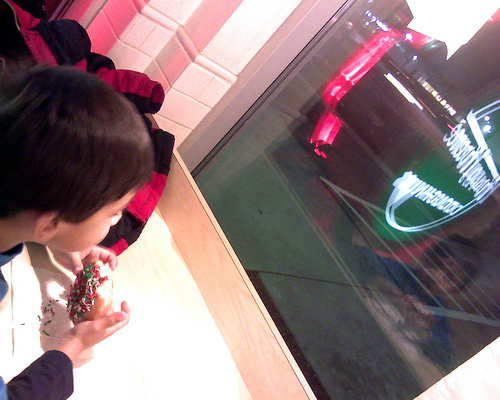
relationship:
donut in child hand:
[66, 260, 114, 326] [62, 248, 132, 353]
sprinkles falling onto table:
[25, 295, 59, 341] [24, 248, 283, 399]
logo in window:
[382, 86, 497, 244] [196, 5, 492, 399]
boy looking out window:
[0, 67, 154, 400] [196, 5, 492, 399]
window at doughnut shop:
[196, 5, 492, 399] [1, 2, 497, 396]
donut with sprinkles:
[66, 260, 114, 326] [83, 265, 94, 287]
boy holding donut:
[0, 67, 154, 400] [66, 260, 114, 326]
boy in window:
[0, 67, 154, 400] [196, 5, 492, 399]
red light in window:
[307, 22, 436, 160] [196, 5, 492, 399]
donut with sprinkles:
[94, 253, 116, 312] [25, 295, 59, 341]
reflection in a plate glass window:
[308, 0, 499, 327] [196, 5, 492, 399]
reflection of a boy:
[358, 228, 481, 358] [0, 67, 154, 400]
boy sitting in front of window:
[0, 67, 154, 400] [196, 5, 492, 399]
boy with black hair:
[0, 67, 154, 400] [0, 65, 155, 224]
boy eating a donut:
[0, 67, 154, 400] [94, 253, 116, 312]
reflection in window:
[358, 228, 481, 358] [196, 5, 492, 399]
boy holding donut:
[3, 59, 159, 273] [94, 253, 116, 312]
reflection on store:
[308, 0, 499, 327] [402, 26, 438, 63]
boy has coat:
[3, 59, 159, 273] [28, 28, 157, 168]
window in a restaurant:
[196, 5, 492, 399] [375, 63, 464, 165]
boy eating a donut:
[3, 59, 159, 273] [94, 253, 116, 312]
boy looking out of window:
[0, 67, 154, 400] [196, 5, 492, 399]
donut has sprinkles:
[94, 253, 116, 312] [25, 295, 59, 341]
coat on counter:
[0, 0, 174, 256] [74, 190, 296, 398]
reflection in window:
[308, 0, 499, 327] [196, 5, 492, 399]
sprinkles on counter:
[25, 295, 59, 341] [74, 190, 296, 398]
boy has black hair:
[3, 59, 159, 273] [67, 99, 121, 143]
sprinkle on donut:
[84, 275, 94, 298] [94, 253, 116, 312]